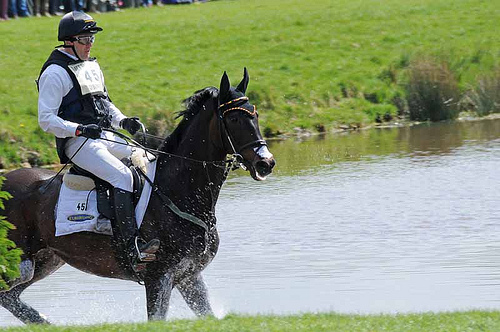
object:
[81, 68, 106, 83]
45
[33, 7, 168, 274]
man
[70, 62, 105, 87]
chest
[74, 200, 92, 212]
45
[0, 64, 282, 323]
horse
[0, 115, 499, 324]
water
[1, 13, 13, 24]
feet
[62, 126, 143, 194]
pants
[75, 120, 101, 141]
gloves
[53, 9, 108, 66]
hat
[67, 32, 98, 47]
googles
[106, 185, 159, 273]
boots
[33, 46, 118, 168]
vest